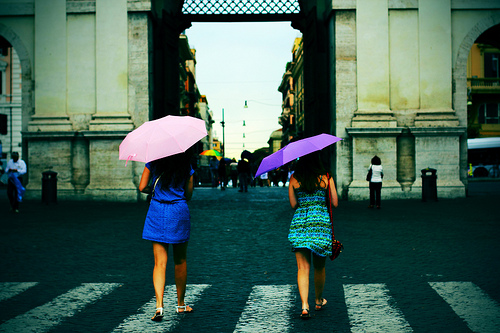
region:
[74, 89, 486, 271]
Two women are carrying umbrellas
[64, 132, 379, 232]
The women are wearing blue dresses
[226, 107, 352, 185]
The umbrella is purple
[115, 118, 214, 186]
The umbrella is pink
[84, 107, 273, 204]
The umbrella is pink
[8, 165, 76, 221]
The man is wearing jeans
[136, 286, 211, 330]
The woman is wearing white sandals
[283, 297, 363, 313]
The woman is wearing black sandals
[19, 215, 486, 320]
White stripes are on the ground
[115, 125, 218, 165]
Person holding pink umbrella.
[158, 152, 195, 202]
Person has black hair.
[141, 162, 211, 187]
Person has long hair.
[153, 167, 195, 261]
Person wearing blue dress.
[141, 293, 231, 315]
Person wearing white sandals.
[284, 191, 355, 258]
Person wearing blue and green dress.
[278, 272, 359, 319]
Person wearing sandals on feet.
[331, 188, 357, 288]
Person holding red bag.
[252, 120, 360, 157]
Person holding purple umbrella.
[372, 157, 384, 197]
Person wearing white shirt.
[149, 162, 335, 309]
two women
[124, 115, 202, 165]
an umbrella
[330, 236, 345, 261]
women carrying a purse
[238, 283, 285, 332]
a shadow on the ground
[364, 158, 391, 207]
a person standing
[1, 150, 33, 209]
a man walking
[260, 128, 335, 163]
the umbrella is purple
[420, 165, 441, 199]
a trashcan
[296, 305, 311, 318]
women is wearing sandals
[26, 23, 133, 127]
a building that is white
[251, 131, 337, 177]
purple umbrella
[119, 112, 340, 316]
two girls in dresses with umbrellas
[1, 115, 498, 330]
two girls walking in a plaza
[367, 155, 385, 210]
tourist studying arch support column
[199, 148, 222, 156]
rainbow colored umbrella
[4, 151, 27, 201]
man in blue jeans and blue shirt relaxing on bench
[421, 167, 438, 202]
metal trash receptacle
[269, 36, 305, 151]
european style buildings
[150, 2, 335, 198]
larged arched gateway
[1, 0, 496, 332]
city plaza with large stone architectural feature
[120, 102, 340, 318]
two womne walking together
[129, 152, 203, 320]
woman wearing blue dress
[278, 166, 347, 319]
woman wearing green dress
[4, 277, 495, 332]
white lines on the walkway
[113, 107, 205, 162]
pink umbrellas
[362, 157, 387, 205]
woman wearing white shirt and black pants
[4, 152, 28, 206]
person wearing white shirt and carrying blue coat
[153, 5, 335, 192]
black entryway onto street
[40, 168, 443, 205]
two black trashcans